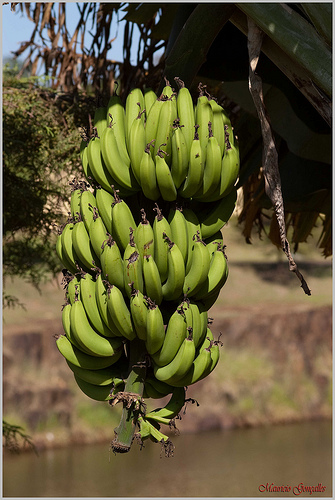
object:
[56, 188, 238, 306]
banana bunch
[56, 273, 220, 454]
banana bunch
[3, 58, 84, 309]
tree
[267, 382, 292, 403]
bush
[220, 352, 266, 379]
bush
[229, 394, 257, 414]
bush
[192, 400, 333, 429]
riverbank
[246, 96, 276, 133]
ground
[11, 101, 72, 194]
leaves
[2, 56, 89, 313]
bush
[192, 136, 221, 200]
banana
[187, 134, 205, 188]
banana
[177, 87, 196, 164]
banana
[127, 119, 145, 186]
banana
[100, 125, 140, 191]
banana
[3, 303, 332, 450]
river bank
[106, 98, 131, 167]
green banana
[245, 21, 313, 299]
leaf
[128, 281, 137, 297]
stem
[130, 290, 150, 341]
banana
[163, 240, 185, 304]
bananas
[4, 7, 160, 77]
blue sky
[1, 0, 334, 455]
banana tree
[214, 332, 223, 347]
stem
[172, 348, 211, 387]
banana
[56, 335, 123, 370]
banana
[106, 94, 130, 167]
banana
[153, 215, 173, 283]
banana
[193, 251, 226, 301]
banana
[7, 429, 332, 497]
river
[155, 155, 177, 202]
banana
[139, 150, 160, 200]
banana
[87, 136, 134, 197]
banana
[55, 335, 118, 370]
banana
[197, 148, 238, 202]
banana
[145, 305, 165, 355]
banana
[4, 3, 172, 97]
leaves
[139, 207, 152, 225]
stem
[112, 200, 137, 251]
banana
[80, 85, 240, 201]
banana bunch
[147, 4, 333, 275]
tree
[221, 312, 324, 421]
bank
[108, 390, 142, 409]
stem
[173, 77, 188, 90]
stem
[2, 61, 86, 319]
greenery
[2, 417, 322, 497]
water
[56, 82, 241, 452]
bunch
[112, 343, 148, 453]
stalk